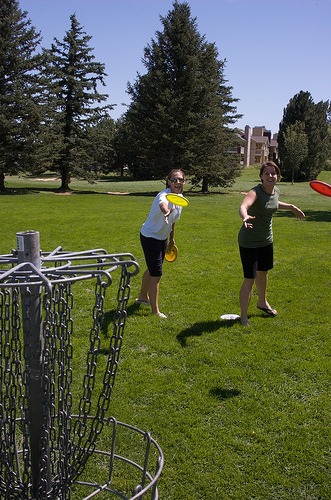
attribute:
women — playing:
[132, 166, 310, 319]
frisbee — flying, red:
[310, 180, 328, 194]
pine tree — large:
[42, 15, 110, 181]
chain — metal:
[77, 286, 107, 437]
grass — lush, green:
[4, 182, 330, 495]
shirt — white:
[142, 189, 184, 242]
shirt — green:
[238, 186, 278, 247]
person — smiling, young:
[238, 163, 308, 321]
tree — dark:
[116, 5, 211, 179]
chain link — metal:
[121, 286, 131, 300]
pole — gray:
[15, 230, 47, 500]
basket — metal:
[7, 412, 160, 498]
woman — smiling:
[139, 171, 189, 318]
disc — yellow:
[168, 192, 189, 208]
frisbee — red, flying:
[307, 179, 330, 201]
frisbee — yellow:
[164, 240, 176, 263]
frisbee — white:
[218, 310, 241, 325]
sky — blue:
[17, 0, 330, 130]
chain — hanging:
[3, 286, 14, 486]